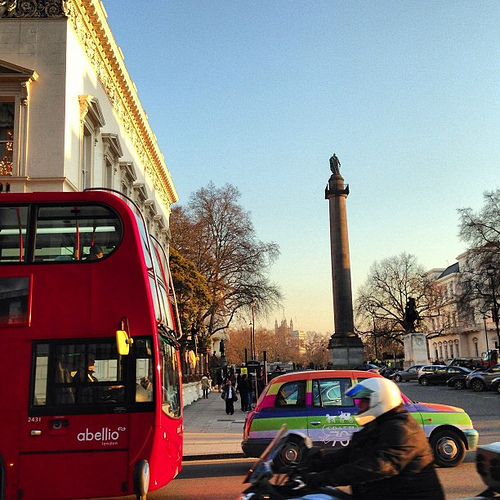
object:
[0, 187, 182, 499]
bus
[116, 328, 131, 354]
mirror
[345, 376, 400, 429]
helmet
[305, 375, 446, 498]
person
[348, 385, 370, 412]
visor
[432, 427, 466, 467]
front wheel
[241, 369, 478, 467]
car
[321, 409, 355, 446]
name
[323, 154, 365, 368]
monument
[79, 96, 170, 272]
windows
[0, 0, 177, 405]
building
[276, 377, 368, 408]
side windows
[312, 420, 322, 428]
door handle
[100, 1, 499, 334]
sky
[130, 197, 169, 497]
edge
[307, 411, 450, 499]
coat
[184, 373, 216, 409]
fence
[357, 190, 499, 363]
trees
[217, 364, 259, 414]
people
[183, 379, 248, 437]
sidewalk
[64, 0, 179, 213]
border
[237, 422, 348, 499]
motorbike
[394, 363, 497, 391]
cars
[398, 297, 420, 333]
statue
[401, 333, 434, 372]
pedestal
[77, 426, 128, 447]
writing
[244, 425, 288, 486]
windshield